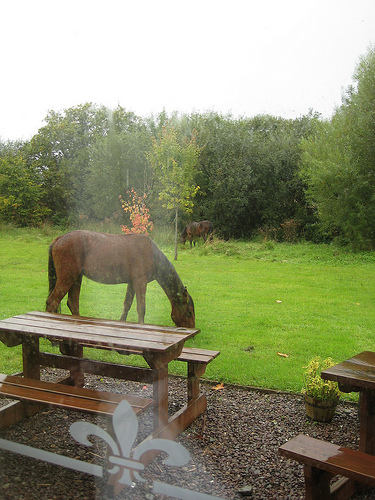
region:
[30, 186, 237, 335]
two horses are grazing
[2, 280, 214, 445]
a picnic table is next to one of t horses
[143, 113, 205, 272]
a small tree in the middle of the yard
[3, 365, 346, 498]
rocks cover the ground in the area of the tables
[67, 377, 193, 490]
a decoration on the window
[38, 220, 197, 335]
the horse is brown in color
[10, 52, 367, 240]
several trees are in the background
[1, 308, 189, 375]
the table appears to be wet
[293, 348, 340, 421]
a potted plant sits in the rocks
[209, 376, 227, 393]
a leaf is in the rocks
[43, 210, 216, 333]
two horses grazing on grass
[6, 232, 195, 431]
a horse standing next to a picnic bench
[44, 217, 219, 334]
two horses in a grassy field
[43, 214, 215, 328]
two horses eating grass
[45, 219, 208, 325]
two horses in a yard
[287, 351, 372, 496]
picnic bench in a backyard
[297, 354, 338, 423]
flower pot near a horse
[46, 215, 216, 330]
two wet horses eating grass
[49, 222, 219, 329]
two horses getting wet in the rain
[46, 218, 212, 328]
two horses grazing on green grass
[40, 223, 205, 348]
brown horse grazing in park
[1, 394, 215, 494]
fluer de lis etched into glass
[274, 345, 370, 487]
edge of wooden bench wet in the rain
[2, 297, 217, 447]
wooden brown bench covered in rain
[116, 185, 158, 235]
red leafed tree in background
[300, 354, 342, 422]
small wooden planter with yellow flowers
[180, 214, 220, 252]
rown horse in background grazing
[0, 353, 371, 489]
stone patch on which benches rest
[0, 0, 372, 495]
picture taken through window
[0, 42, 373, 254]
forest of thick green trees in background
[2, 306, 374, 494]
Two brown picnic tables.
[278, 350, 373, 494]
One wooden picnic table.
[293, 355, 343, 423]
Planter with yellow flowers.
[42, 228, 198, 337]
Horse grazing in a yard.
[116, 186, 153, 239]
Small tree with fall colored leaves.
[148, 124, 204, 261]
One tree in the yard.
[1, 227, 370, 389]
Green grassy yard.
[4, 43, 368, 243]
Trees bordering the edge of the yard.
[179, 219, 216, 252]
Horse in front of a wooded area.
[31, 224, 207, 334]
horse leaning over in grass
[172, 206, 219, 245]
horse leaning over in grass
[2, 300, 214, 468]
bench with table on rocks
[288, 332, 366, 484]
bench with table on rocks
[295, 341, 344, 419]
pot filled with plants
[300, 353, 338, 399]
plants in the pot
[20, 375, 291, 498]
rocks in the seating area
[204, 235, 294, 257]
clumps on grass near horse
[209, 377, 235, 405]
leaf on the ground